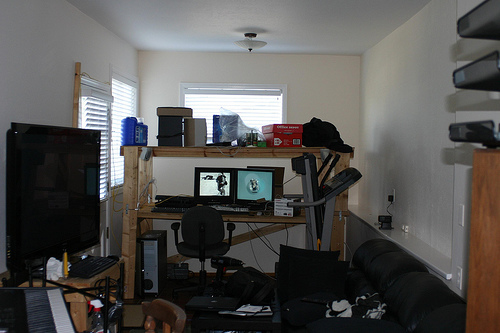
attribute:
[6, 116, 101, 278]
tv — large, flat screen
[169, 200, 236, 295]
chair — rolling, office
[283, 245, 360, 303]
cushion — dark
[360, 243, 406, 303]
cushion — dark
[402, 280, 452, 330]
cushion — dark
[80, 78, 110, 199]
blinds — white, Venetian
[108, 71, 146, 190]
blinds — Venetian, white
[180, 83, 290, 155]
blinds — white, Venetian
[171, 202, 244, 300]
chair — office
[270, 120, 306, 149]
box — red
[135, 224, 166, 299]
tower — computer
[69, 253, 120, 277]
keyboard — black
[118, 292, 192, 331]
chair — wooden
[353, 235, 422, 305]
cushion — brown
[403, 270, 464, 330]
cushion — brown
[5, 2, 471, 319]
room — small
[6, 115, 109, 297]
tv — off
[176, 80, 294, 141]
blinds — open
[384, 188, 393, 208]
plug — black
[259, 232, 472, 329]
couch — black, large 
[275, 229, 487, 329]
couch — Black 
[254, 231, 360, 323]
pillows — Black 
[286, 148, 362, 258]
exercise machine — gray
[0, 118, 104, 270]
television — big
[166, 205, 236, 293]
desk chair — black and gray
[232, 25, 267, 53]
ceiling lamp — small, white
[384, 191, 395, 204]
wall charger — black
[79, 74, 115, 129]
window — white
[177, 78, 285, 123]
window — white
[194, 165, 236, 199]
computer screen — black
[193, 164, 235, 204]
computer screen — black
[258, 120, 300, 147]
box — red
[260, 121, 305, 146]
box — red, rectangular